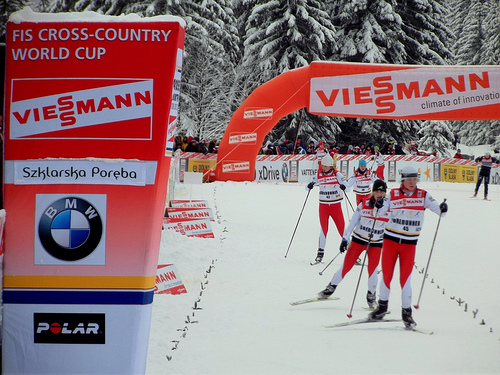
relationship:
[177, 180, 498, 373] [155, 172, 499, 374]
path in snow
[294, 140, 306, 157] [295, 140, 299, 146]
person has a head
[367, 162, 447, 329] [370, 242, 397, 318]
skier has a leg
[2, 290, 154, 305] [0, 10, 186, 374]
stripe on a sign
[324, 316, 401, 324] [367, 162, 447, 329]
ski on a skier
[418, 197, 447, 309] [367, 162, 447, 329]
ski pole for skier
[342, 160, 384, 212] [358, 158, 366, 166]
skier has a cap